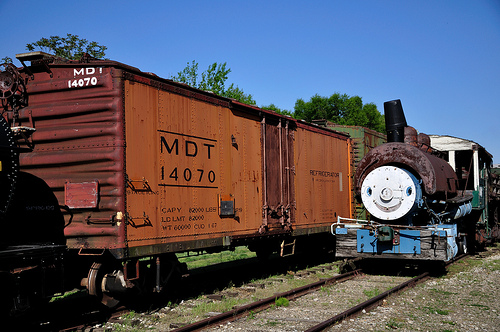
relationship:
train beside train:
[333, 99, 499, 278] [12, 58, 369, 277]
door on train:
[260, 117, 292, 231] [0, 52, 391, 325]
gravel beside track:
[85, 227, 499, 329] [296, 232, 498, 329]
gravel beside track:
[85, 227, 499, 329] [166, 262, 366, 330]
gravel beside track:
[85, 227, 499, 329] [26, 298, 130, 329]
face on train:
[348, 157, 423, 224] [340, 80, 497, 288]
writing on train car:
[152, 122, 221, 194] [1, 41, 397, 322]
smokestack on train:
[379, 95, 413, 146] [334, 99, 480, 266]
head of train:
[362, 140, 455, 220] [331, 100, 496, 274]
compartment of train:
[2, 54, 352, 259] [1, 45, 392, 312]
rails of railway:
[181, 265, 452, 330] [3, 43, 497, 330]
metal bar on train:
[335, 212, 378, 223] [276, 66, 498, 321]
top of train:
[32, 53, 350, 140] [1, 45, 392, 312]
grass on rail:
[275, 293, 290, 309] [163, 267, 439, 330]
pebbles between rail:
[203, 271, 414, 330] [182, 267, 362, 329]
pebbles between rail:
[203, 271, 414, 330] [307, 274, 424, 330]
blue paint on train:
[338, 192, 482, 252] [320, 127, 498, 271]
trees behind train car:
[34, 33, 387, 125] [13, 52, 354, 282]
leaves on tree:
[288, 94, 385, 128] [294, 92, 394, 130]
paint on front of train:
[370, 169, 403, 184] [287, 95, 497, 310]